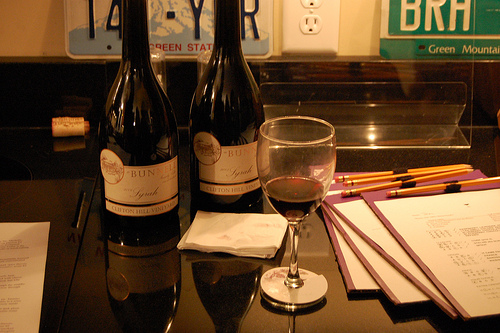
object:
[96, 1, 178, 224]
bottle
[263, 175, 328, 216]
wine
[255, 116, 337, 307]
glass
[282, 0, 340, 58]
receptacle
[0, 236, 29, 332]
black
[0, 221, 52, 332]
paper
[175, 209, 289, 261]
napkins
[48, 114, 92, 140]
cork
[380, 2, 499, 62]
license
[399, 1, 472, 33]
white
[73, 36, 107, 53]
blue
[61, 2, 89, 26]
white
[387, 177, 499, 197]
pencils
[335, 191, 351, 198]
erasers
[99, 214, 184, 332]
reflection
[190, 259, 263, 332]
reflection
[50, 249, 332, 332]
black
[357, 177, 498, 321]
set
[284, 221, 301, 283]
clear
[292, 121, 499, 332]
table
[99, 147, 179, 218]
lable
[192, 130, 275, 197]
lable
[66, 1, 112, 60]
section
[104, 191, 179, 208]
line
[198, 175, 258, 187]
line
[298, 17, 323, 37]
plug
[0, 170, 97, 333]
table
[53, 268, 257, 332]
table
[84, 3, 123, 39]
numbers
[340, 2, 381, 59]
wall